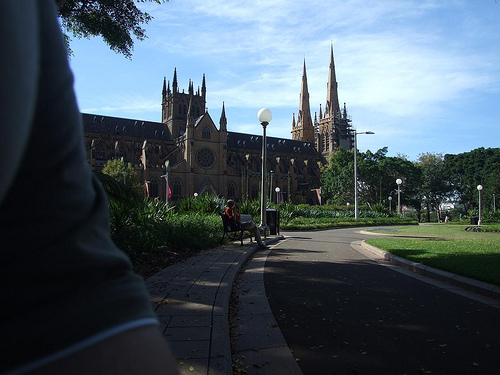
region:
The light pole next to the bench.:
[259, 108, 275, 228]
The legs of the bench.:
[217, 230, 257, 241]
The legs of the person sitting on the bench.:
[246, 223, 268, 253]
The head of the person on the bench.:
[225, 198, 233, 205]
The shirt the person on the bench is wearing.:
[227, 206, 240, 224]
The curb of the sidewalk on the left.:
[216, 235, 265, 372]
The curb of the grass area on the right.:
[357, 240, 498, 302]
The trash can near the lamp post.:
[263, 208, 279, 234]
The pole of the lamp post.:
[258, 120, 266, 237]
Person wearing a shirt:
[0, 2, 160, 372]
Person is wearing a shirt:
[0, 0, 160, 373]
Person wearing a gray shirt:
[0, 0, 165, 371]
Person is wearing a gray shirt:
[0, 0, 163, 372]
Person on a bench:
[222, 195, 270, 255]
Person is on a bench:
[215, 190, 272, 250]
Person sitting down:
[221, 191, 274, 249]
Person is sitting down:
[217, 190, 272, 252]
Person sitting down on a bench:
[215, 192, 274, 252]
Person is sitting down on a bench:
[219, 195, 276, 254]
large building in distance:
[58, 78, 368, 210]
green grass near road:
[347, 213, 496, 292]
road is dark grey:
[297, 245, 340, 291]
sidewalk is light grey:
[165, 260, 211, 332]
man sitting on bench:
[227, 208, 274, 265]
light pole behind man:
[244, 110, 286, 227]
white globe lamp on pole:
[240, 89, 271, 138]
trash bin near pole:
[262, 203, 277, 235]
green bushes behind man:
[107, 156, 250, 270]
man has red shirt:
[219, 206, 252, 231]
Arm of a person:
[0, 0, 179, 374]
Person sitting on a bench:
[224, 195, 269, 251]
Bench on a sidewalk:
[220, 208, 262, 248]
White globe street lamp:
[255, 103, 276, 238]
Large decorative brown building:
[77, 40, 359, 207]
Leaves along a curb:
[227, 262, 252, 372]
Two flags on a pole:
[142, 171, 172, 203]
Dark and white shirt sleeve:
[0, 3, 162, 372]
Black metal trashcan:
[265, 207, 282, 236]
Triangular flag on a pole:
[311, 187, 324, 206]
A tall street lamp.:
[252, 101, 277, 241]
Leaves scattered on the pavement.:
[251, 288, 383, 363]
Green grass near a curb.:
[442, 236, 484, 281]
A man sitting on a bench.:
[211, 198, 265, 248]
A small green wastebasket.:
[265, 200, 282, 236]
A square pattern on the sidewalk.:
[145, 273, 220, 328]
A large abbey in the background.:
[97, 52, 340, 233]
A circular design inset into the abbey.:
[193, 144, 220, 173]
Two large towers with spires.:
[293, 38, 363, 193]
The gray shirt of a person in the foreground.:
[4, 12, 178, 373]